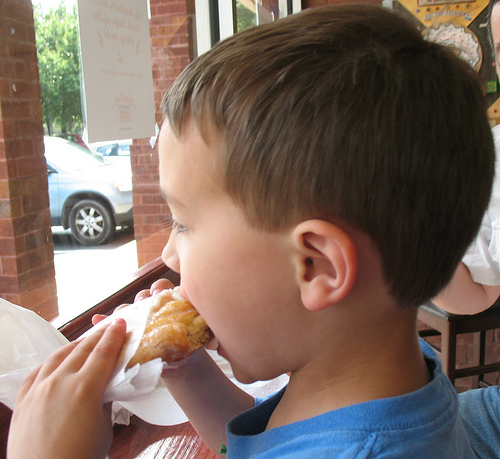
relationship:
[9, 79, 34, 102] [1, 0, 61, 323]
brick on beam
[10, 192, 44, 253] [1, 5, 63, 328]
bricks on beam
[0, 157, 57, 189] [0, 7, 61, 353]
bricks on beam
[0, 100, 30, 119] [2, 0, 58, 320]
brick on beam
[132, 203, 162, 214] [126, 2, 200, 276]
brick on beam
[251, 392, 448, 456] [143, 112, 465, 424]
t-shirt on boy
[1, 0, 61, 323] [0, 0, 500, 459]
beam on restaurant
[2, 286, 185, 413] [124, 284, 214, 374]
waxed paper holding food